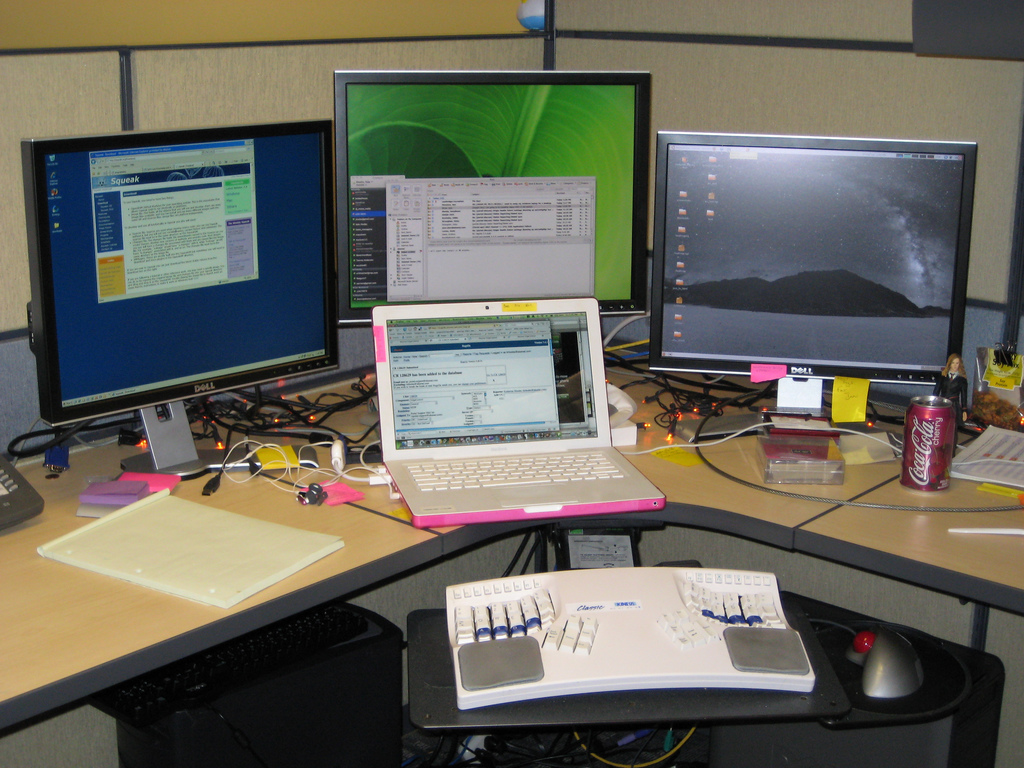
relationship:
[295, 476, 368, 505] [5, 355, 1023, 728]
pad on desk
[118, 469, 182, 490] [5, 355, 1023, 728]
pad on desk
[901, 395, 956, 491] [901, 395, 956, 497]
can of can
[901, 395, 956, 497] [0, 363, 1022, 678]
can on a desk